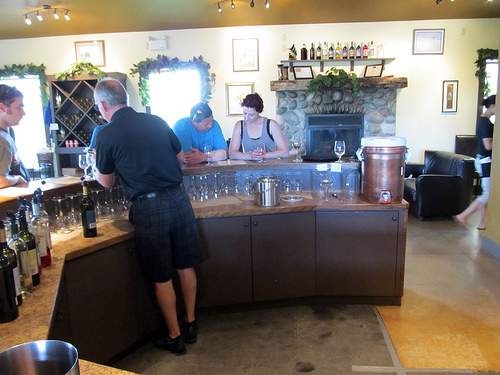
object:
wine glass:
[334, 140, 345, 163]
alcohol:
[79, 176, 97, 237]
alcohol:
[31, 197, 51, 266]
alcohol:
[14, 209, 40, 287]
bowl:
[0, 340, 78, 375]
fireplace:
[270, 77, 411, 155]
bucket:
[253, 176, 280, 206]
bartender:
[92, 77, 204, 357]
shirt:
[95, 106, 182, 200]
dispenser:
[355, 134, 410, 204]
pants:
[129, 186, 207, 284]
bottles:
[6, 210, 34, 299]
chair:
[404, 150, 477, 222]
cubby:
[51, 79, 109, 147]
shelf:
[280, 58, 394, 67]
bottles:
[289, 42, 374, 60]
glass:
[50, 196, 72, 234]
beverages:
[364, 178, 405, 206]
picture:
[441, 80, 458, 111]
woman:
[452, 95, 495, 232]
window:
[483, 59, 500, 125]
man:
[172, 102, 229, 164]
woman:
[228, 93, 289, 160]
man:
[0, 84, 26, 188]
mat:
[101, 305, 398, 374]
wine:
[82, 198, 98, 235]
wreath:
[129, 54, 217, 107]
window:
[146, 67, 202, 128]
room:
[0, 0, 499, 374]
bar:
[0, 163, 360, 215]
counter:
[0, 158, 361, 207]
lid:
[360, 136, 407, 147]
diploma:
[413, 30, 444, 55]